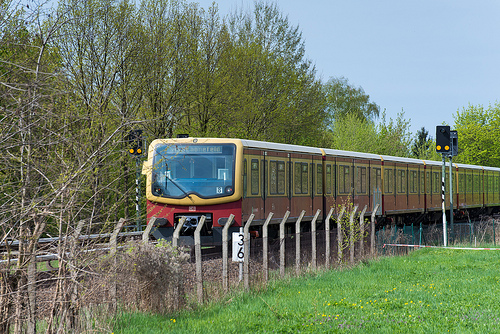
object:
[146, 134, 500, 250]
train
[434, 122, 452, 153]
light signal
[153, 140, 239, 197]
windshield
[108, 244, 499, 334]
grass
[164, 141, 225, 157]
digital  board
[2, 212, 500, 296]
tracks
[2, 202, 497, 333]
fence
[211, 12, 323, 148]
tree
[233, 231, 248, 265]
sign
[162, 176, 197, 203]
windshield wiper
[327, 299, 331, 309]
flower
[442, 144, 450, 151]
lights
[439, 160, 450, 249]
pole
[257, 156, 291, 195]
windows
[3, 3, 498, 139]
sky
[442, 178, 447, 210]
stripes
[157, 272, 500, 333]
flowers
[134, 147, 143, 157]
lights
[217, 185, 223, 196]
8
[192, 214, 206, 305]
post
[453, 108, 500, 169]
trees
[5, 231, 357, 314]
pebbles